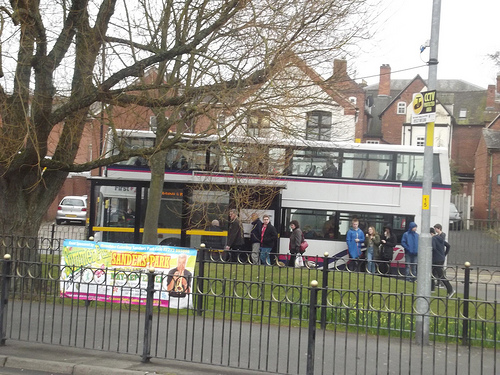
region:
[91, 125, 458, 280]
A double decker bus.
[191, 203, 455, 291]
People grouped next to the bus.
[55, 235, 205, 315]
A banner on the fence.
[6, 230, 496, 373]
A metal fence.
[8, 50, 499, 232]
Houses on the far side of the road.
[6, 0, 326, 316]
A tree by the road.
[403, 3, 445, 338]
A metal pole with a sign on it.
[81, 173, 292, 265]
A bus stop.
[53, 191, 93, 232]
A car parked by the house.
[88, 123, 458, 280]
A large white bus in the road.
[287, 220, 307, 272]
a woman wearing a brown coat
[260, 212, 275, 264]
a woman wearing a black coat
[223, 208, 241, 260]
a man wearing a jacket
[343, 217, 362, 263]
a boy wearing a blue jacket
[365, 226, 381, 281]
a girl wearing a green jacket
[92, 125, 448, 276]
a white double decker bus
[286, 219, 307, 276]
a woman and a shoulder purse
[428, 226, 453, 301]
a man wearing shoes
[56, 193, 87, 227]
a silver car parked by brick building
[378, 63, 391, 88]
a brick chimney atop a building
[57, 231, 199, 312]
banner hanging on the fence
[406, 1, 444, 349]
lamp post pole on sidewalk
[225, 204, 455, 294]
people waiting for bus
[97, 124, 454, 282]
white double decker bus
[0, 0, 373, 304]
large leafless tree in park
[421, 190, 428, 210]
yellow sticker on lamp post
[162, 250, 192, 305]
man playing trumpet on banner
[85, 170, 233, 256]
glass bus stop with yellow stripe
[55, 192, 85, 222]
small silver coupe parked in driveway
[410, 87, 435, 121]
sign hanging on lamp post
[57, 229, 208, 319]
a billboard on a fence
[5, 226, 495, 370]
a fence on the side of the street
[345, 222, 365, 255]
a blue sweatshirt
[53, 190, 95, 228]
back of a silver car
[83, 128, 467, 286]
a white and red double decker bus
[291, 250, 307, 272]
a plastic shopping bag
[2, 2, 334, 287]
a dead tree with long branches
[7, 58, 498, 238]
brick houses lining the street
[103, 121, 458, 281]
a white bus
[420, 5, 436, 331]
a silver pole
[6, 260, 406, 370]
a black fence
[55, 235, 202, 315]
a sign on the fence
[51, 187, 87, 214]
a silver car behind the bus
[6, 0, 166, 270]
trees next to the bus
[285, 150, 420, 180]
the window of the bus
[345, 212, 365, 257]
a person in a blue jacket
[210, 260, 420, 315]
grass in front of the bus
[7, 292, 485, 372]
sidewalk in between the fences